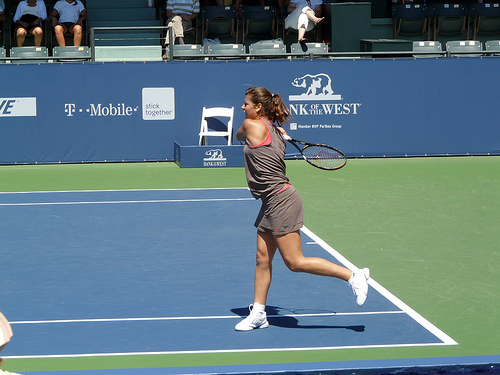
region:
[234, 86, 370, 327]
a woman playing tennis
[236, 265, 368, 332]
a woman wearing white shoes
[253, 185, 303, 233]
woman wearing a gray short skirt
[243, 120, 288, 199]
woman wearing a gray tank top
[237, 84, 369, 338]
woman swinging her tennis racket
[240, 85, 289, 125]
woman with brown hair in a pony tail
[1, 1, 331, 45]
spectators in the bleachers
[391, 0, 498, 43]
empty blue seats in the bleachers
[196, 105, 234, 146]
a white folding chair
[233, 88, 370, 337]
a woman ready to hit a ball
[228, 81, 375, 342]
Young girl playing tennis.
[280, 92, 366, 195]
Black tennis racket.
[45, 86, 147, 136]
Phone company ad on the wall.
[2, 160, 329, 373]
Blue, hard tennis court.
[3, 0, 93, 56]
People watching tennis match.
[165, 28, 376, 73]
Front row seats.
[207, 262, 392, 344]
White shoes on girl.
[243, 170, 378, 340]
Young girl wearing skirt.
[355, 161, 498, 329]
Green portion of tennis court.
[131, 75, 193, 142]
Sign that says stick together.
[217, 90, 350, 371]
This is a picture of a woman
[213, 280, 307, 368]
These are tennis shoes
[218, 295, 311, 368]
The shoes are white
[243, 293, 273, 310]
These are socks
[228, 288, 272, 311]
The socks are white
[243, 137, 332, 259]
This is a grey jumpsuit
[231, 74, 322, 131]
This is a ponytail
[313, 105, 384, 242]
This is a racket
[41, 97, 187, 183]
These are ads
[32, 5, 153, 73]
These are fans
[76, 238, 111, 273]
Blue part of the tennis court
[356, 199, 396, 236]
Green part of tennis court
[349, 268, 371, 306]
Left white shoe of tennis player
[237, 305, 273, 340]
Right white shoe of tennis player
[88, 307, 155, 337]
Solid white line on tennis court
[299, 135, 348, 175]
Black and yellow tennis racket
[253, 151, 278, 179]
Gray shirt of female tennis player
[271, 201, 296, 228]
Gray shorts of female tennis player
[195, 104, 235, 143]
White chair in the distance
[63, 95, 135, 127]
T-Mobile's logo on banner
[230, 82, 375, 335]
a woman playing tennis on a tennis court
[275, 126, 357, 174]
a tennis racket on a tennis court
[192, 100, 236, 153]
a white chair on a tennis court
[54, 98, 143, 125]
words on a sign on a tennis court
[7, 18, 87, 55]
two people's knees sitting at a tennis court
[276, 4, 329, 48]
a person bending over at a tennis court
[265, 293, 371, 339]
a shadow of a woman on a tennis court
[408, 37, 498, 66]
metal chairs at a tennis court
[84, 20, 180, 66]
a railing at a tennis court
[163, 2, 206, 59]
knees of a person sitting at a tennis court